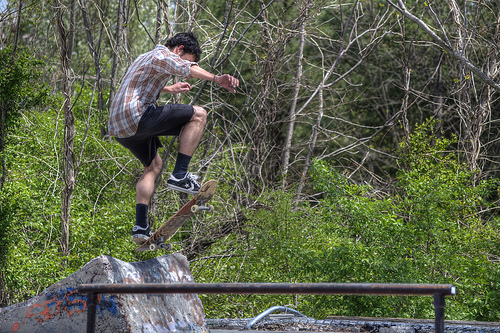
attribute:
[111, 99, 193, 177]
shorts — black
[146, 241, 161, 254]
wheel — beige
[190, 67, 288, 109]
arms — extended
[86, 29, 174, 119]
shirt — plaid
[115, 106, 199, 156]
shorts — black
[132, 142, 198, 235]
shoes — black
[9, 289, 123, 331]
graffati — red, blue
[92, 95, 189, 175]
shorts — black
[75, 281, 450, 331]
rail — long, rusty, brown, metal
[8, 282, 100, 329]
graffiti — orange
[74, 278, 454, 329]
skateboard railing — rusty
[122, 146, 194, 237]
socks — black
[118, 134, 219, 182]
sock — black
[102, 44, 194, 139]
shirt — plaid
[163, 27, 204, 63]
hair — black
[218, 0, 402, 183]
trees — leafless